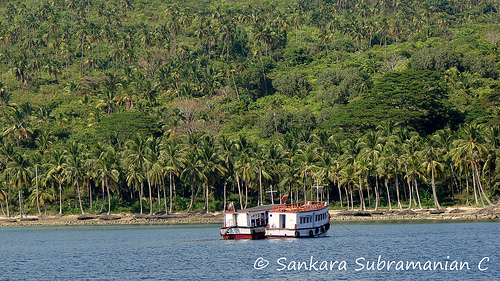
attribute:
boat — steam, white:
[224, 193, 332, 240]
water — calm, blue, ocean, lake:
[3, 224, 498, 277]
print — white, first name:
[253, 258, 495, 273]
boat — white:
[222, 203, 258, 239]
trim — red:
[225, 234, 257, 242]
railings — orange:
[276, 207, 327, 212]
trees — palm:
[3, 167, 499, 213]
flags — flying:
[225, 202, 236, 216]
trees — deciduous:
[344, 74, 433, 122]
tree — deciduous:
[96, 106, 158, 138]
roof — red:
[277, 206, 335, 214]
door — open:
[279, 213, 287, 229]